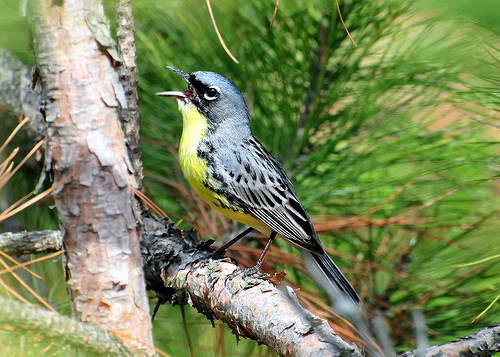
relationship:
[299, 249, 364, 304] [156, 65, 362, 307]
tail of bird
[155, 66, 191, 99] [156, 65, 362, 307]
beak of bird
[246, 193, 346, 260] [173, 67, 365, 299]
feathers on bird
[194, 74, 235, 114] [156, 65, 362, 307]
eye of bird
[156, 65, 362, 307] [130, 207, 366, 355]
bird on branch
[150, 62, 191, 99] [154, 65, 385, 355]
beak of bird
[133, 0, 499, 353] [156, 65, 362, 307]
palm fronds behind bird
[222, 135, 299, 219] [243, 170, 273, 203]
blue feathers with black markings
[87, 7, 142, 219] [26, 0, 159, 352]
bark peeling off trunk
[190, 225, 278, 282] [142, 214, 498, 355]
legs slanted across branch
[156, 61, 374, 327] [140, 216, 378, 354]
bird on branch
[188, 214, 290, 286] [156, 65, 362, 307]
legs on bird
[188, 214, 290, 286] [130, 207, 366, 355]
legs on branch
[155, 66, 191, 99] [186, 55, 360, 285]
beak on bird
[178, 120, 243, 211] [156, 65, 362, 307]
chest on bird